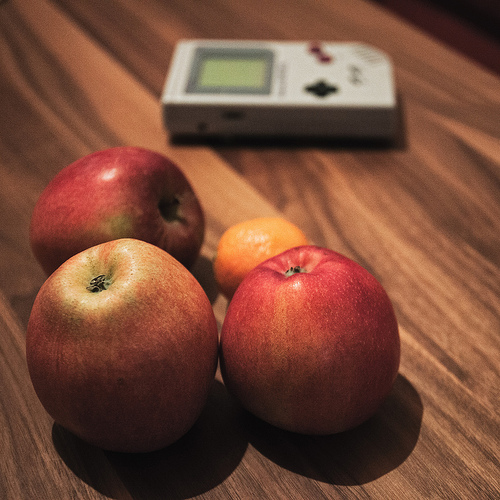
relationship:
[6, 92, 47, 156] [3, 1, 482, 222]
grain in table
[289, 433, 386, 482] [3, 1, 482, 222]
shadow on table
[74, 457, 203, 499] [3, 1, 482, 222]
shadow on table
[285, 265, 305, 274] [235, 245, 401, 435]
stem of apple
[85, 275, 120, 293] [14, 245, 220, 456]
stem on apple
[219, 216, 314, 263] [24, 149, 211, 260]
orange next to apple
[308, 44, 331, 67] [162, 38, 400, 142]
dot on device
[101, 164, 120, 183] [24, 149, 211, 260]
light reflecting on apple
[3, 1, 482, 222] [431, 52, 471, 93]
table made of wood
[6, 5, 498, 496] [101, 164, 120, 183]
room has light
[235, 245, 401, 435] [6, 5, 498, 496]
apple in room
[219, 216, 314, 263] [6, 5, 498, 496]
orange in room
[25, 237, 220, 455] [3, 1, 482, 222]
apple on table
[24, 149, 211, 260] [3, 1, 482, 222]
apple on table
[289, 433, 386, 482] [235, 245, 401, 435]
shadow of apple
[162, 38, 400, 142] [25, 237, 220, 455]
device next apple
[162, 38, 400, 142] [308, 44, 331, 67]
device has dot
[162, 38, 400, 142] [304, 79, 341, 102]
device has cross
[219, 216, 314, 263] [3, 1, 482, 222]
orange on table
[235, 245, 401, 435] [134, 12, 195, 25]
apple facing up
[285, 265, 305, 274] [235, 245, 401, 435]
stem on apple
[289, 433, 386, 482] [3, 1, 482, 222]
shadow across table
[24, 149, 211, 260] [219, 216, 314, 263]
apple hiding orange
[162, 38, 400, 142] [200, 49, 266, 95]
device has square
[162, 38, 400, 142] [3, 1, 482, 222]
device on table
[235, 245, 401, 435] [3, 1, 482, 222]
apple on table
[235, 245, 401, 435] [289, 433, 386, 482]
apple casting shadow